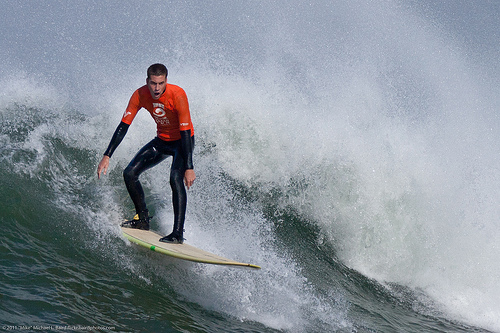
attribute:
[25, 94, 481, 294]
wave — ocean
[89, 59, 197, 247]
man — black, surfer, wet, surfing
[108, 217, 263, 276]
surfboard — tan, green, white, beige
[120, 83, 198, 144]
t-shirt — red, white, orange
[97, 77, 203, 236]
body suit — orange, black, black orange, long sleeved, white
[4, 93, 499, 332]
ocean — rough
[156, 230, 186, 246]
surf shoe — black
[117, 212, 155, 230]
surf shoe — black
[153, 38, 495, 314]
mist — white, spraying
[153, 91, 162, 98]
mouth — open, wide open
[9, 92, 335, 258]
wave — rough, wild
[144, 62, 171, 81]
hair — short, brown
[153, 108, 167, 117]
logo — white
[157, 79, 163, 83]
eye brow — black, bushy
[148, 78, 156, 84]
eye brow — black, bushy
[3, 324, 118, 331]
lettering — white